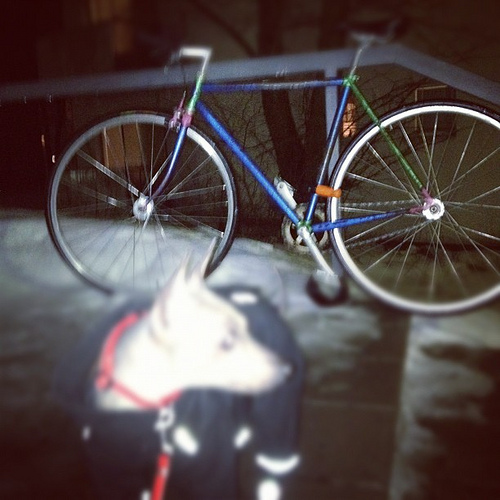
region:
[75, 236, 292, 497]
small white dog with a red collar and leash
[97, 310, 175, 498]
red collar and leash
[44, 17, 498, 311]
blue bicycle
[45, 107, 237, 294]
front tire of the bicycle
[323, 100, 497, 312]
bicycle's rear tire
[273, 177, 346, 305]
two bicycle pedals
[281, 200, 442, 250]
silver bicycle chain on a bik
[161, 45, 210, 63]
front handle bars on a bike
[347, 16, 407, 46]
black leather bike seat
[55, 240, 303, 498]
white dog dressed in a dark outfit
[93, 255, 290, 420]
tan short hair dog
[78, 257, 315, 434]
small dog looking right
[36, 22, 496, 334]
blue metal frame bicycle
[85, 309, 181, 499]
red nylon dog collar with leash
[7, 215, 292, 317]
pile of snow under bike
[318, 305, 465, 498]
snow covered cement porch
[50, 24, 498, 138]
silver metal porch rail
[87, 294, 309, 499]
black shirt for dogs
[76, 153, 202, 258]
silver bicycle tire spokes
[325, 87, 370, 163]
lighted distant house window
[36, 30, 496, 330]
a blue bike is parked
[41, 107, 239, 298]
front wheel of bike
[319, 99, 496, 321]
back wheel of bike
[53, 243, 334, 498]
a white dog in front a bike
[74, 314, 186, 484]
red collar of dog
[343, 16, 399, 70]
sit of dog is black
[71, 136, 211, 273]
spokes of wheel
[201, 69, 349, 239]
a triangle formed with tubes of bike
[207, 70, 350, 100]
top tube is blue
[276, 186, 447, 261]
chain of bike is color silver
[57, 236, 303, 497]
A blurry dog is looking right.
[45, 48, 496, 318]
A blue and green bicycle sitting.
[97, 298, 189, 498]
A red leash attacked to a dog.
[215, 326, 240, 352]
The dog has a black eye.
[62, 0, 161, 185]
There are lit windows in the background.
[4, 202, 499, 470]
A sidewalk under a dog.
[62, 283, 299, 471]
The dog is dressed in blue.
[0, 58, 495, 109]
A metal rail behind a bike.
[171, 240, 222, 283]
Two ears pointing towards something.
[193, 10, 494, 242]
A tree with no leaves.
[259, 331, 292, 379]
edge of a coat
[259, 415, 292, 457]
part of a sleeve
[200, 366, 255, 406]
edge of a jacket